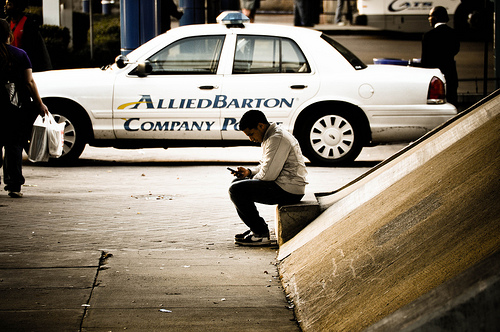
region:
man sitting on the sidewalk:
[214, 109, 310, 256]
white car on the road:
[10, 9, 468, 180]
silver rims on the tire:
[301, 111, 361, 163]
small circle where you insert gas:
[357, 82, 379, 99]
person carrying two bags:
[2, 27, 74, 193]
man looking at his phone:
[214, 104, 314, 254]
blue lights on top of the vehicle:
[215, 3, 247, 28]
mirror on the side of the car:
[132, 56, 157, 78]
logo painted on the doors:
[117, 86, 294, 146]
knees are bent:
[223, 176, 251, 207]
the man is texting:
[178, 77, 333, 277]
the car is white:
[27, 14, 479, 170]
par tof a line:
[76, 272, 109, 306]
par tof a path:
[183, 275, 223, 308]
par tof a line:
[82, 274, 97, 295]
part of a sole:
[248, 240, 267, 249]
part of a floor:
[110, 263, 127, 279]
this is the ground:
[95, 155, 157, 189]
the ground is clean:
[117, 170, 182, 208]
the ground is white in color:
[107, 175, 188, 193]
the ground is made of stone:
[58, 260, 161, 312]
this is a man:
[220, 107, 318, 242]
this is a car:
[58, 13, 435, 145]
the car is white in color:
[388, 85, 415, 116]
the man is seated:
[221, 110, 314, 236]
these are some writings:
[111, 85, 218, 131]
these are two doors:
[182, 38, 303, 69]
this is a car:
[114, 34, 391, 136]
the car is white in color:
[356, 78, 406, 100]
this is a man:
[209, 96, 302, 247]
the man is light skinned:
[248, 125, 258, 142]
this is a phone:
[224, 162, 237, 179]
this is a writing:
[133, 92, 333, 118]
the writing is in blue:
[135, 94, 211, 111]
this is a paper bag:
[45, 120, 66, 157]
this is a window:
[168, 37, 216, 68]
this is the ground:
[65, 160, 195, 308]